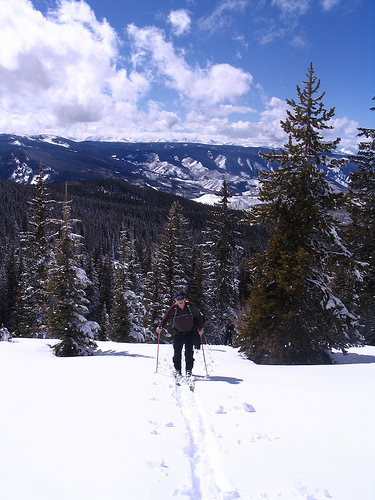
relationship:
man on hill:
[156, 289, 205, 380] [0, 336, 374, 498]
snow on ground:
[49, 381, 181, 461] [6, 331, 374, 497]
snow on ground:
[52, 372, 332, 486] [6, 331, 374, 497]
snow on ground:
[0, 360, 373, 495] [6, 331, 374, 497]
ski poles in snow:
[154, 322, 161, 375] [0, 336, 373, 497]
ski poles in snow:
[197, 326, 211, 379] [0, 336, 373, 497]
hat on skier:
[167, 294, 201, 302] [154, 289, 207, 389]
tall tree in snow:
[234, 53, 367, 366] [0, 336, 373, 497]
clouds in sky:
[3, 1, 374, 155] [3, 1, 367, 155]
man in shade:
[157, 289, 203, 382] [175, 296, 184, 299]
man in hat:
[157, 289, 203, 382] [173, 289, 184, 298]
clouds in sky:
[3, 1, 374, 155] [0, 19, 355, 148]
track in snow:
[174, 398, 189, 414] [11, 364, 139, 480]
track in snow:
[203, 424, 223, 443] [11, 364, 139, 480]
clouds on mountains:
[3, 1, 374, 155] [0, 134, 372, 207]